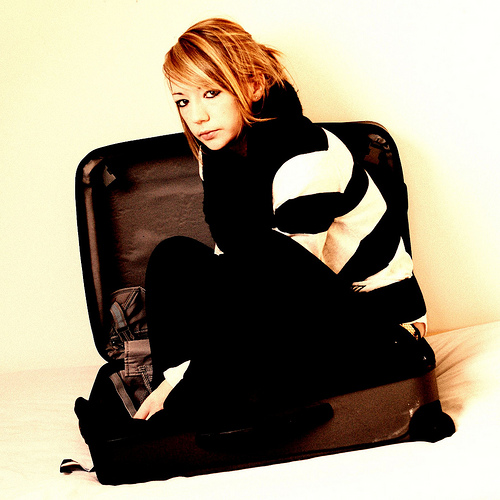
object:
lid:
[74, 118, 416, 366]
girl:
[132, 15, 440, 436]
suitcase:
[58, 118, 461, 491]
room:
[0, 0, 500, 499]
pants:
[136, 223, 441, 442]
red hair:
[161, 17, 302, 166]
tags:
[57, 456, 98, 482]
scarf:
[197, 79, 333, 268]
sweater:
[196, 123, 433, 346]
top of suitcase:
[74, 120, 406, 175]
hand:
[131, 378, 179, 423]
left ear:
[247, 69, 267, 103]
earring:
[254, 96, 259, 100]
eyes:
[202, 87, 224, 101]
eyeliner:
[202, 87, 222, 98]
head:
[161, 18, 274, 154]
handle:
[193, 400, 335, 453]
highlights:
[156, 14, 300, 169]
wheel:
[406, 405, 456, 444]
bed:
[0, 319, 499, 499]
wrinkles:
[433, 351, 475, 380]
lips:
[198, 127, 224, 137]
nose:
[189, 93, 211, 125]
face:
[170, 76, 242, 152]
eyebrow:
[170, 91, 186, 98]